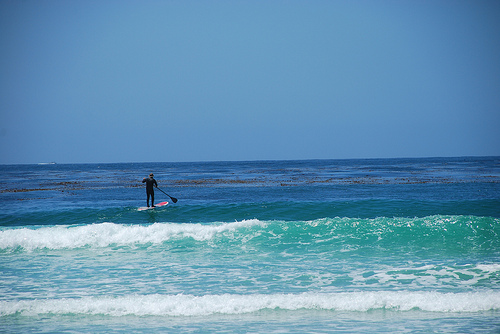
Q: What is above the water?
A: Sky.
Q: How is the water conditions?
A: Wavy.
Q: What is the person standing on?
A: Paddle board.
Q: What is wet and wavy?
A: The water.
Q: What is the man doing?
A: Surfing.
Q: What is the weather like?
A: Clear skies.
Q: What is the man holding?
A: Paddle.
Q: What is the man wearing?
A: Wetsuit.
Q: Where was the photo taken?
A: The ocean.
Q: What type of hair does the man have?
A: Short hair.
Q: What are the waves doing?
A: Crashing.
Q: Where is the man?
A: Middle of the water.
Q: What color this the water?
A: Blue /green.